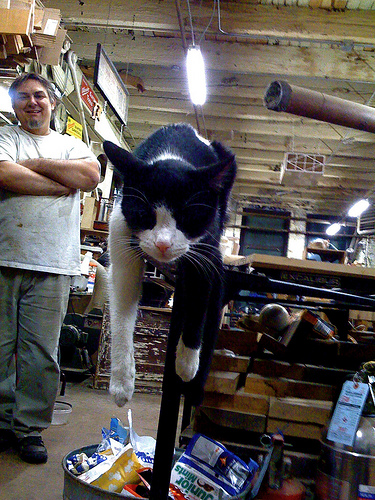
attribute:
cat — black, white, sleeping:
[87, 112, 243, 415]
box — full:
[54, 420, 334, 500]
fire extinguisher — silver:
[311, 353, 372, 499]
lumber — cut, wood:
[209, 337, 345, 446]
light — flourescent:
[171, 42, 221, 112]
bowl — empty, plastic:
[50, 396, 78, 428]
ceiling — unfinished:
[79, 5, 370, 150]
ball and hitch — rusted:
[236, 298, 335, 392]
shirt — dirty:
[1, 125, 93, 285]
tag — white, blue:
[316, 370, 372, 457]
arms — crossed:
[1, 139, 107, 204]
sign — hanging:
[83, 41, 137, 131]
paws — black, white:
[96, 342, 210, 415]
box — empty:
[114, 411, 166, 472]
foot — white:
[108, 385, 136, 413]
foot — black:
[174, 291, 211, 382]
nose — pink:
[151, 234, 173, 262]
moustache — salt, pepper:
[20, 105, 50, 131]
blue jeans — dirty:
[0, 260, 84, 436]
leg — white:
[101, 249, 141, 402]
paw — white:
[100, 344, 145, 411]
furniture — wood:
[184, 254, 374, 313]